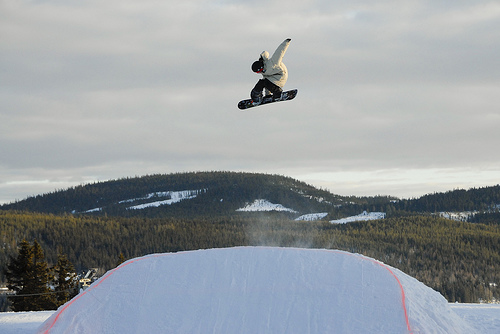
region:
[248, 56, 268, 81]
head of a person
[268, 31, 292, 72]
arm of a person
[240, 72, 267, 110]
leg of a person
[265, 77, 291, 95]
leg of a person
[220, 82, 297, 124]
person on a board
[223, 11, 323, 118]
person in mid air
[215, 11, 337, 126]
person wearing a jacket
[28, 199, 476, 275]
bunch of trees in the background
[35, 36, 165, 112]
a sky full of clouds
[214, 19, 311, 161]
a person that is on a snowboard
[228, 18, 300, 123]
a person that is jumping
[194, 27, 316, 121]
a snowboarder that is jumping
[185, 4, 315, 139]
a person wearing a jacket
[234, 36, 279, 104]
a snowboarder wearing a jacket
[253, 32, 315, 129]
a person wearing a white jacket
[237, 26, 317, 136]
a snowboarder wearing a white jacket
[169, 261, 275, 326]
a ground covered in snow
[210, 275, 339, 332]
white snow covering the ground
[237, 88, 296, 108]
the black and white snowboard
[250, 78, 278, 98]
the black pair of ski pants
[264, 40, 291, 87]
a white and black ski jacket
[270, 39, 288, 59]
the arm of a jacket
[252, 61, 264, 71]
a black plastic helmet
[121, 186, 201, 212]
a patch of snow in the distance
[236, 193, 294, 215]
a patch of snow in the distance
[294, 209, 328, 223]
a patch of snow in the distance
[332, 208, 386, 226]
a patch of snow in the distance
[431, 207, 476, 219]
a patch of snow in the distance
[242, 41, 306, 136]
snowboarder is in the air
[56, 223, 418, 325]
a snow halfpipe on the ground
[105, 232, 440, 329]
ramp made of snow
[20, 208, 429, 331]
the edges of snow are orange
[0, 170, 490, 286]
mountain range in the distance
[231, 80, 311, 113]
the snowboard is black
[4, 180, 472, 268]
the mountains have little snow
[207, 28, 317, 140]
flying through the air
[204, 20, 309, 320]
just jumped off the ramp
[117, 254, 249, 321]
a ground covered in snow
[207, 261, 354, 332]
ground covered in white snow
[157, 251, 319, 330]
snow covering the ground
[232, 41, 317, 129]
a person in the air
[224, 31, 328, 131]
a person that is jumping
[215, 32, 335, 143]
a snowboarder doing a jump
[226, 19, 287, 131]
a snowboarder wearing a jacket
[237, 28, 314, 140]
a person wearing a jacket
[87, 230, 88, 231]
A green leaf on a plant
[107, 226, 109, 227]
A green leaf on a plant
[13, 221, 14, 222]
A green leaf on a plant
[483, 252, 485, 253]
A green leaf on a plant